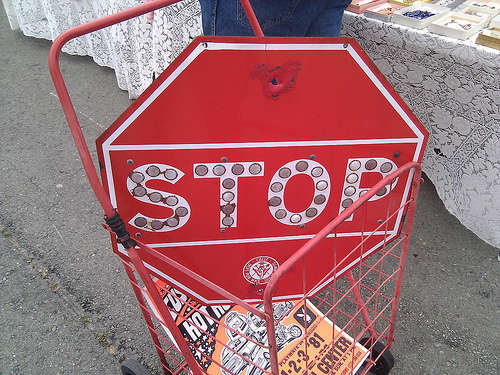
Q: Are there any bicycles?
A: No, there are no bicycles.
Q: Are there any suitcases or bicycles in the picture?
A: No, there are no bicycles or suitcases.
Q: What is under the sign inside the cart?
A: The poster is under the sign.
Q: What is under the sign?
A: The poster is under the sign.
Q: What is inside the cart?
A: The sign is inside the cart.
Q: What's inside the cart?
A: The sign is inside the cart.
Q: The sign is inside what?
A: The sign is inside the cart.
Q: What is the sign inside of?
A: The sign is inside the cart.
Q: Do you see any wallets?
A: No, there are no wallets.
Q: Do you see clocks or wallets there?
A: No, there are no wallets or clocks.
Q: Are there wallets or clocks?
A: No, there are no wallets or clocks.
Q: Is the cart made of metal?
A: Yes, the cart is made of metal.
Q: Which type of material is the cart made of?
A: The cart is made of metal.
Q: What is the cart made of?
A: The cart is made of metal.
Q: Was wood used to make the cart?
A: No, the cart is made of metal.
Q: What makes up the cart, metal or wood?
A: The cart is made of metal.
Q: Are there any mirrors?
A: No, there are no mirrors.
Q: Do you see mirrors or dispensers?
A: No, there are no mirrors or dispensers.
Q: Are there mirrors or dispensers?
A: No, there are no mirrors or dispensers.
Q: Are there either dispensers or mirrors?
A: No, there are no mirrors or dispensers.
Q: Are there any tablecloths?
A: Yes, there is a tablecloth.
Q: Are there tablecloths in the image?
A: Yes, there is a tablecloth.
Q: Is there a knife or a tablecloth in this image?
A: Yes, there is a tablecloth.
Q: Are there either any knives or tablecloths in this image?
A: Yes, there is a tablecloth.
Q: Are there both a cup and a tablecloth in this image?
A: No, there is a tablecloth but no cups.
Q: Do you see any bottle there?
A: No, there are no bottles.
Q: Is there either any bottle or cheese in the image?
A: No, there are no bottles or cheese.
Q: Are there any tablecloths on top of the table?
A: Yes, there is a tablecloth on top of the table.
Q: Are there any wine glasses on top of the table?
A: No, there is a tablecloth on top of the table.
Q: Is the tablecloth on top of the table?
A: Yes, the tablecloth is on top of the table.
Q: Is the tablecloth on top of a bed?
A: No, the tablecloth is on top of the table.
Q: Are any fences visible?
A: No, there are no fences.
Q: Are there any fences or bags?
A: No, there are no fences or bags.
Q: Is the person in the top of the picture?
A: Yes, the person is in the top of the image.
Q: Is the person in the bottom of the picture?
A: No, the person is in the top of the image.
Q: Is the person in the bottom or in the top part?
A: The person is in the top of the image.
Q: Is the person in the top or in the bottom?
A: The person is in the top of the image.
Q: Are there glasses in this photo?
A: No, there are no glasses.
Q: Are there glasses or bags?
A: No, there are no glasses or bags.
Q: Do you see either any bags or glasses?
A: No, there are no glasses or bags.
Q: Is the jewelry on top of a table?
A: Yes, the jewelry is on top of a table.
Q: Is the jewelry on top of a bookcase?
A: No, the jewelry is on top of a table.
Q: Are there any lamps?
A: No, there are no lamps.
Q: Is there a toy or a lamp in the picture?
A: No, there are no lamps or toys.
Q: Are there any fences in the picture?
A: No, there are no fences.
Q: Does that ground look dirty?
A: Yes, the ground is dirty.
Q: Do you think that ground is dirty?
A: Yes, the ground is dirty.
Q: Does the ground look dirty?
A: Yes, the ground is dirty.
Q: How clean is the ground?
A: The ground is dirty.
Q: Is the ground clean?
A: No, the ground is dirty.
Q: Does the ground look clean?
A: No, the ground is dirty.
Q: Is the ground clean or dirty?
A: The ground is dirty.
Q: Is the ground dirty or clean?
A: The ground is dirty.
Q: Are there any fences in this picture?
A: No, there are no fences.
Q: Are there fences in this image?
A: No, there are no fences.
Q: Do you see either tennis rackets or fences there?
A: No, there are no fences or tennis rackets.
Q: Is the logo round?
A: Yes, the logo is round.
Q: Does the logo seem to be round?
A: Yes, the logo is round.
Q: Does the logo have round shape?
A: Yes, the logo is round.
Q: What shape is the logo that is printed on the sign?
A: The logo is round.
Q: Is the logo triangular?
A: No, the logo is round.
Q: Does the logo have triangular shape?
A: No, the logo is round.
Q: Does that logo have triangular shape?
A: No, the logo is round.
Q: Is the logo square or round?
A: The logo is round.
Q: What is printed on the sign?
A: The logo is printed on the sign.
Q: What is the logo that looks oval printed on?
A: The logo is printed on the sign.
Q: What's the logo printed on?
A: The logo is printed on the sign.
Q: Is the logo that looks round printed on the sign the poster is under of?
A: Yes, the logo is printed on the sign.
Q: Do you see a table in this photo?
A: Yes, there is a table.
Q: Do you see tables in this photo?
A: Yes, there is a table.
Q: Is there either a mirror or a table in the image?
A: Yes, there is a table.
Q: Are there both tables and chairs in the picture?
A: No, there is a table but no chairs.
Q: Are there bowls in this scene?
A: No, there are no bowls.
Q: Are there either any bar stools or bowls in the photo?
A: No, there are no bowls or bar stools.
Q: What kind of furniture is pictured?
A: The furniture is a table.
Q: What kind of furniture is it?
A: The piece of furniture is a table.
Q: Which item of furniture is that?
A: That is a table.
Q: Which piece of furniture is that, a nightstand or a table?
A: That is a table.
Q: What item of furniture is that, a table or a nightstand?
A: That is a table.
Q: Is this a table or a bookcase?
A: This is a table.